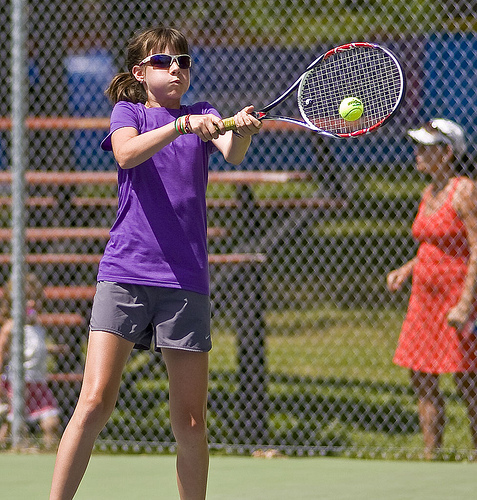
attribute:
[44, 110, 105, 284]
bleacher — stadium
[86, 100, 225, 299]
shirt — purple, short sleeve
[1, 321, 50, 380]
shirt — white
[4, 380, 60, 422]
shorts — pink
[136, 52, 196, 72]
sunglasses — pair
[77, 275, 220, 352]
shorts — blue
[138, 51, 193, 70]
sunglasses — girl's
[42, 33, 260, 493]
girl — playing tennis, little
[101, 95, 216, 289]
shirt — purple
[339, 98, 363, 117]
tennis ball — green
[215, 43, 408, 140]
tennis racket — large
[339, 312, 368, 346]
grass — green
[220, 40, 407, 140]
racket — red , black 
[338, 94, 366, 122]
tennis ball — green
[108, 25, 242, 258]
girl — little 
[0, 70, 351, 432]
bleachers — red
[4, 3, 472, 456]
fence — metal, chain link, grey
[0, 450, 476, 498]
tennis court — green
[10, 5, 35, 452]
fence post — metallic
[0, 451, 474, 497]
court — tennis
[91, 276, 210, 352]
shorts — dark blue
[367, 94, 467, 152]
hat — white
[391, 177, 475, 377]
sundress — melon colored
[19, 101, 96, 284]
bleachers — wooden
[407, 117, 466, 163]
cap — white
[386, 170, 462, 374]
dress — red